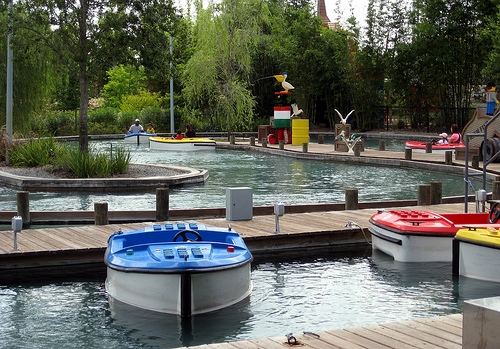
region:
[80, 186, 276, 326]
A blue and white boat.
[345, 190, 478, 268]
A red and white boat.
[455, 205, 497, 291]
A yellow and white boat.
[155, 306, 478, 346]
Wooden dock next to the boats.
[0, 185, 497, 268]
Another dock behind the boats.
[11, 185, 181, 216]
A few wooden poles.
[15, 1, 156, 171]
A tree next to the water.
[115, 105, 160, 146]
People in a boat.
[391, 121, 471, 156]
Another boat with people.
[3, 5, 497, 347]
People are sailing in tiny boats.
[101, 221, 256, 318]
A small blue, gray and black boat on the water.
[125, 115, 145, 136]
A man in a gray shirt on a gray boat.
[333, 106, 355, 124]
A white bird on a crate with it's wings extended.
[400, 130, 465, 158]
A red and gray boat with two people inside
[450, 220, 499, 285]
The end of a yellow boat.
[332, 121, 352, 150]
A brown crate with a white bird on it.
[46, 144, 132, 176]
A group of green grass on a little island.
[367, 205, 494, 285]
A red and yellow boat together on the water.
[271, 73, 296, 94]
A white bird with a large yellow beak and feet.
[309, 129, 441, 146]
Water near two people in a red and gray boat.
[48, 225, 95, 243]
this is the walking path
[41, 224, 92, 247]
the path is made of wood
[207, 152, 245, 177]
this is the water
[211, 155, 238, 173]
the water is blue in color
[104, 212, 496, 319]
these are some boats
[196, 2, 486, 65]
these are some trees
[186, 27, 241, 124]
the leaves are green in color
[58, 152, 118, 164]
this is the grass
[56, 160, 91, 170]
the grass is green in color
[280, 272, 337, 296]
the water has some ripples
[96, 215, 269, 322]
a blue and white boat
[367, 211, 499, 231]
the top of the boat is red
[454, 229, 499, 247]
the top of the boat is yellow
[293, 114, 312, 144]
the can is yellow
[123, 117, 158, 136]
the man and child are in the boat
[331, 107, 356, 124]
the birds wings are in mid flight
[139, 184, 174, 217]
wooden posts are in the water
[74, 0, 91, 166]
a tree is in the center of the bushes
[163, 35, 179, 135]
the lamp post is white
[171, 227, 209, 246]
the steering wheel is black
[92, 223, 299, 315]
a blue boat carnival ride in water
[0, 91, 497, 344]
a group of boats sitting in water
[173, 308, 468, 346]
a brown wooden dock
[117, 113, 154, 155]
a person in the distance riding in a boat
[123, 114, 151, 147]
a person in distance is wearing a grey hoodie and riding in a white and blue boat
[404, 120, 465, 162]
two people are riding in a red and white boat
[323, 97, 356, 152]
a bird is sitting on top of a brick post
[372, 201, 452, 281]
a red empty boat sitting in water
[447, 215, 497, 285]
a yellow empty boat sitting empty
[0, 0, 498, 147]
a bunch of trees sitting in background